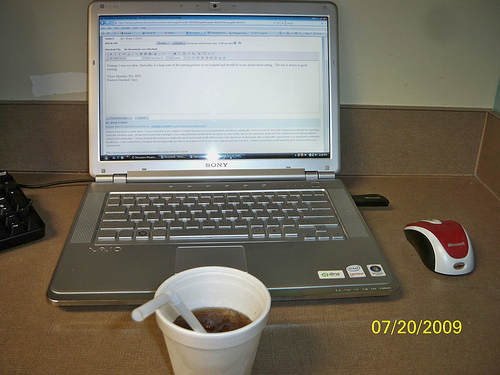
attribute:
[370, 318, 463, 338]
number — yellow, print number, prints number, near right corner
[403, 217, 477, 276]
mouse — wireless, red,white, black, red,black, white, red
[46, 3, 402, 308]
computer — grey, laptop, silver, gray, black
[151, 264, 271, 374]
cup — white, styrofoam, plastic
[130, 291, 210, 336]
straw — bent, white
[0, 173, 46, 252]
keyboard — black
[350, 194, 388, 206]
usb drive — black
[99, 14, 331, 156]
screen — on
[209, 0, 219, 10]
webcam — built in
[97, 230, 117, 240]
button — silver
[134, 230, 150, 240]
button — silver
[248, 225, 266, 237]
button — silver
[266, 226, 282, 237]
button — silver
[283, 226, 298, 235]
button — silver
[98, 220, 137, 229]
button — silver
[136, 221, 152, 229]
button — silver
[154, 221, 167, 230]
button — silver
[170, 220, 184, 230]
button — silver